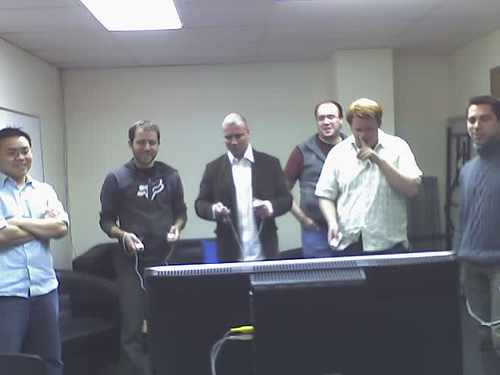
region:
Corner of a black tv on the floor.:
[144, 256, 165, 287]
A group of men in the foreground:
[0, 90, 498, 370]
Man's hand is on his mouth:
[345, 118, 382, 169]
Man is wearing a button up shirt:
[315, 121, 428, 263]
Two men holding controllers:
[107, 193, 274, 294]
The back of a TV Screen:
[128, 245, 479, 373]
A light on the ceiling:
[71, 1, 201, 49]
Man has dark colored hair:
[458, 93, 498, 150]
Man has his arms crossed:
[1, 175, 78, 302]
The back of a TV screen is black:
[136, 243, 468, 373]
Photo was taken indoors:
[3, 0, 496, 373]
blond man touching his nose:
[313, 98, 421, 253]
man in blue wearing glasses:
[1, 127, 69, 373]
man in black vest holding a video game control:
[195, 113, 292, 263]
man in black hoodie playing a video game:
[100, 120, 187, 373]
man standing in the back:
[284, 100, 351, 257]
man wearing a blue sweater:
[456, 97, 498, 374]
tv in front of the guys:
[145, 250, 462, 373]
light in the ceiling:
[78, 0, 182, 30]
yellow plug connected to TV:
[230, 326, 255, 333]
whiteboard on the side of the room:
[0, 105, 47, 184]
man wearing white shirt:
[341, 95, 417, 257]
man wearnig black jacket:
[200, 115, 297, 251]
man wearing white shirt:
[195, 115, 302, 257]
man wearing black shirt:
[95, 105, 191, 257]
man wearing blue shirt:
[10, 120, 61, 365]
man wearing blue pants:
[0, 125, 72, 355]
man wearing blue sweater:
[440, 95, 496, 357]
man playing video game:
[341, 96, 426, 252]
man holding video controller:
[191, 103, 276, 254]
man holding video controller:
[116, 113, 180, 261]